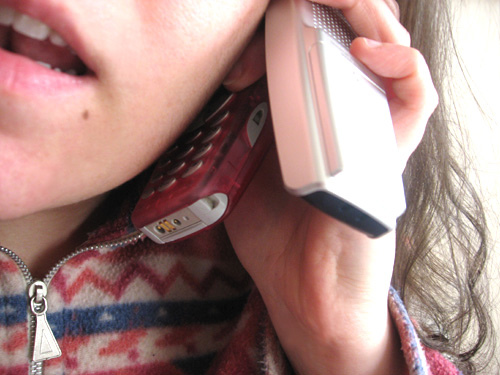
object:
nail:
[362, 36, 384, 49]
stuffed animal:
[296, 6, 385, 37]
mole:
[79, 106, 93, 121]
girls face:
[0, 0, 265, 218]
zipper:
[23, 273, 67, 364]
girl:
[1, 0, 500, 371]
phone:
[265, 0, 409, 240]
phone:
[129, 83, 272, 245]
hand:
[218, 0, 440, 375]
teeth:
[0, 12, 94, 75]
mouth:
[0, 0, 107, 96]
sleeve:
[342, 286, 476, 375]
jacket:
[0, 157, 478, 375]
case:
[127, 73, 273, 244]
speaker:
[294, 1, 364, 48]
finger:
[350, 34, 440, 129]